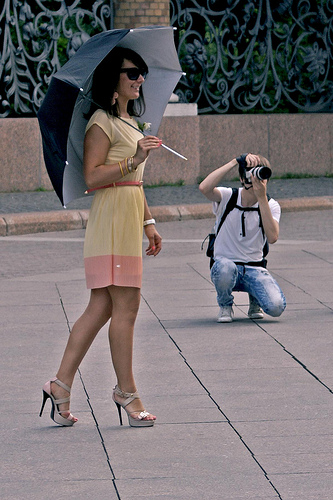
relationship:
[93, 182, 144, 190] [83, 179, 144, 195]
belt on belt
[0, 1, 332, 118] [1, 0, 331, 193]
metal frame of wall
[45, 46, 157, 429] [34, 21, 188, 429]
woman holding umbrella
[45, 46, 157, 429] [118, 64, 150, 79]
woman wearing sunglasses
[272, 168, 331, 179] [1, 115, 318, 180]
grass growing along wall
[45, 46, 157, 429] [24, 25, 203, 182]
woman holding umbrella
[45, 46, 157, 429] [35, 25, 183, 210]
woman holding umbrella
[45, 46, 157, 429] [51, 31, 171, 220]
woman holding umbrella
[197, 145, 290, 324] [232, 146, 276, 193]
man holding camera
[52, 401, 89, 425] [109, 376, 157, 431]
feet in sandals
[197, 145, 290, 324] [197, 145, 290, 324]
man squatting man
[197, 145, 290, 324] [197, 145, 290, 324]
man taking photo man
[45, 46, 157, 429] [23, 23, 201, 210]
woman with umbrella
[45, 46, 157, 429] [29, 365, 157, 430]
woman wearing high heels